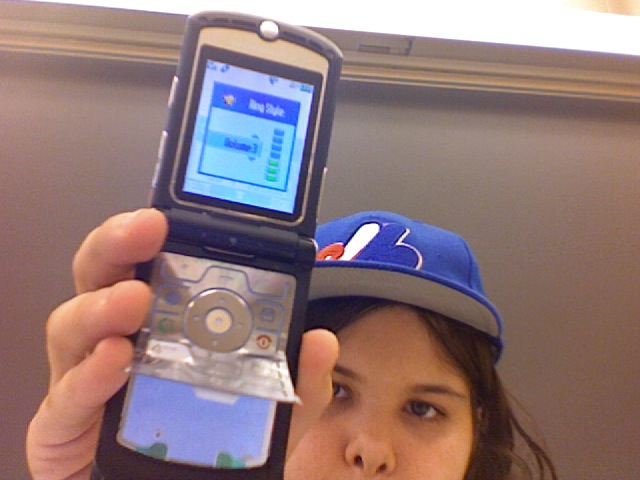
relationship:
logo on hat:
[329, 209, 432, 269] [351, 212, 473, 312]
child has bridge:
[24, 208, 556, 480] [344, 385, 396, 474]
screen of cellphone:
[180, 59, 315, 214] [93, 9, 345, 477]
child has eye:
[24, 208, 556, 480] [401, 397, 445, 420]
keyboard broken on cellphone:
[124, 251, 303, 408] [88, 10, 345, 480]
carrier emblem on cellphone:
[256, 16, 280, 43] [88, 10, 345, 480]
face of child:
[283, 308, 472, 477] [24, 208, 556, 480]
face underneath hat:
[283, 308, 472, 477] [304, 207, 502, 366]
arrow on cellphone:
[214, 292, 232, 311] [88, 10, 345, 480]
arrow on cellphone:
[231, 319, 248, 334] [88, 10, 345, 480]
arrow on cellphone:
[207, 337, 223, 355] [88, 10, 345, 480]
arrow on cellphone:
[189, 316, 202, 326] [88, 10, 345, 480]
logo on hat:
[315, 222, 423, 270] [304, 207, 502, 366]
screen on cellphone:
[180, 59, 315, 214] [93, 9, 345, 477]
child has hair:
[24, 209, 556, 477] [299, 294, 558, 477]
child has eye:
[24, 209, 556, 477] [328, 378, 351, 400]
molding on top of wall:
[5, 5, 639, 96] [6, 54, 633, 477]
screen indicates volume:
[182, 50, 316, 231] [210, 131, 277, 158]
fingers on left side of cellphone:
[26, 193, 180, 468] [88, 10, 345, 480]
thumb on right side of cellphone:
[289, 314, 342, 455] [88, 10, 345, 480]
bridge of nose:
[329, 385, 411, 472] [346, 395, 405, 477]